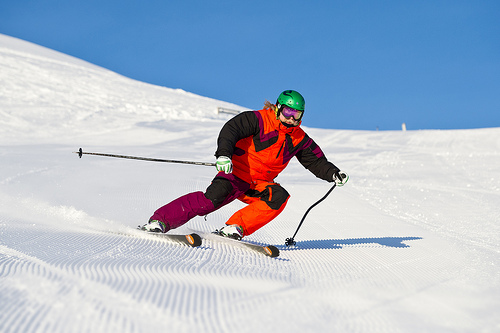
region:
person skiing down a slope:
[70, 86, 349, 265]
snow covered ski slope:
[3, 28, 498, 332]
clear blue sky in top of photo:
[3, 0, 498, 126]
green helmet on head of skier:
[274, 88, 303, 131]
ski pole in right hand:
[71, 145, 228, 170]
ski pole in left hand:
[282, 177, 340, 247]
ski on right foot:
[125, 219, 205, 249]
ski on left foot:
[199, 226, 281, 256]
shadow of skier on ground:
[276, 233, 425, 252]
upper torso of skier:
[216, 113, 306, 185]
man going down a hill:
[132, 77, 357, 328]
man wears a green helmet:
[256, 77, 314, 147]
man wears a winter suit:
[129, 77, 354, 247]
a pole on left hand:
[286, 169, 351, 251]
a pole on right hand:
[69, 137, 239, 177]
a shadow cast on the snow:
[261, 222, 426, 260]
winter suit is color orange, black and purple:
[136, 87, 353, 257]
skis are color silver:
[126, 222, 286, 258]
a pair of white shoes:
[134, 217, 246, 239]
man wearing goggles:
[271, 104, 304, 128]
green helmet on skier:
[274, 89, 311, 123]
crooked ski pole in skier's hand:
[286, 162, 346, 255]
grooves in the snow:
[80, 242, 195, 331]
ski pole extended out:
[61, 144, 236, 182]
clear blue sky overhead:
[307, 10, 474, 100]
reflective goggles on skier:
[276, 103, 307, 123]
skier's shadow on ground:
[254, 235, 423, 259]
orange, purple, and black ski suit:
[149, 105, 354, 237]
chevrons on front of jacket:
[252, 121, 306, 165]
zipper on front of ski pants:
[266, 184, 274, 204]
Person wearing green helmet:
[258, 83, 320, 143]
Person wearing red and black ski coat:
[208, 64, 345, 200]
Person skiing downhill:
[60, 59, 355, 282]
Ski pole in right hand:
[62, 133, 248, 195]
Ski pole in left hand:
[280, 170, 355, 255]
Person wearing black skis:
[130, 222, 294, 265]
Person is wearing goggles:
[266, 99, 308, 124]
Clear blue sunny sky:
[112, 20, 464, 80]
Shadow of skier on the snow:
[243, 217, 438, 270]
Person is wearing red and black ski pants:
[131, 159, 295, 251]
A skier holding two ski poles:
[66, 82, 357, 268]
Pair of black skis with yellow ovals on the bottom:
[125, 220, 281, 267]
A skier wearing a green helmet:
[136, 83, 353, 253]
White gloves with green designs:
[211, 153, 352, 188]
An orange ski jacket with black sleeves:
[203, 100, 347, 194]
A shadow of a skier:
[250, 227, 424, 260]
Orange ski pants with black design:
[137, 166, 293, 242]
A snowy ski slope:
[1, 29, 498, 332]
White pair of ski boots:
[130, 215, 246, 245]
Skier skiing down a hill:
[136, 79, 350, 267]